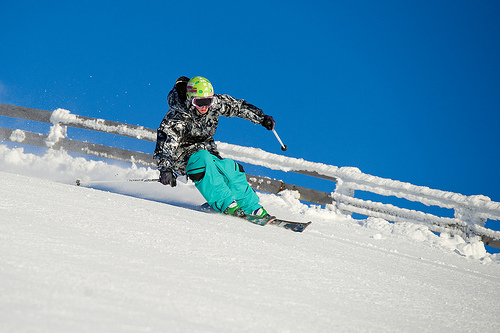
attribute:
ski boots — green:
[222, 201, 267, 220]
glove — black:
[248, 108, 277, 130]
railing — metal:
[1, 101, 498, 251]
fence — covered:
[286, 130, 498, 280]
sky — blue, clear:
[0, 1, 499, 249]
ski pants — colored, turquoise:
[183, 147, 267, 226]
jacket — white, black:
[137, 89, 296, 172]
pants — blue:
[185, 150, 262, 212]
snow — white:
[344, 164, 489, 202]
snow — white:
[0, 144, 498, 330]